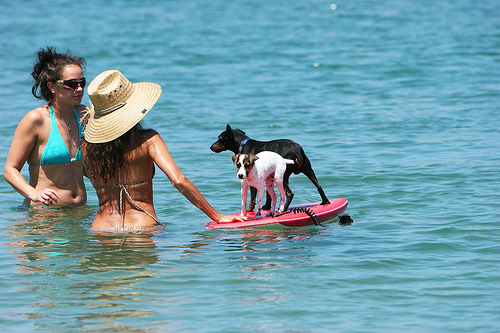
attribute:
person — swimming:
[80, 70, 247, 233]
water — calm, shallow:
[1, 1, 499, 331]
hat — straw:
[82, 69, 163, 145]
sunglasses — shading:
[53, 77, 86, 91]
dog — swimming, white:
[231, 151, 297, 219]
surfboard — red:
[204, 196, 348, 231]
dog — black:
[208, 123, 331, 212]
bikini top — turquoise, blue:
[28, 106, 84, 167]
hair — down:
[81, 122, 144, 183]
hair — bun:
[31, 47, 87, 102]